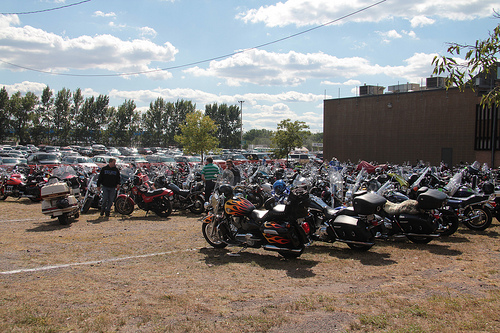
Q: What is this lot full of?
A: Motorcycles and cars.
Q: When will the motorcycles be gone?
A: When their owners drive away with them.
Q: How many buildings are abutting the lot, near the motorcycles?
A: One.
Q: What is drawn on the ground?
A: A white line.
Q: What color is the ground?
A: Brown.